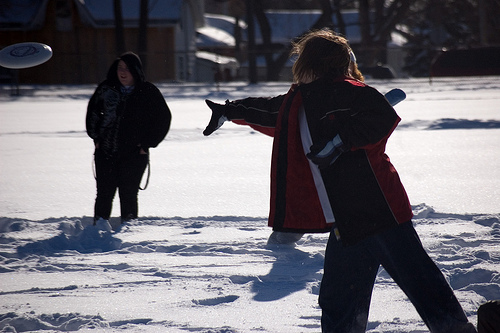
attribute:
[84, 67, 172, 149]
coat — black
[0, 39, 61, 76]
frisbee — flying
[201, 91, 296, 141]
arm — out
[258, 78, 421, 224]
jacket — red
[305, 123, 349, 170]
gloves — black, white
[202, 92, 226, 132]
gloves — black, white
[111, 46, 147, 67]
hood — black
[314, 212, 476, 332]
pants — black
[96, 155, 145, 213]
pants — black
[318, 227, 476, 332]
pants — pair , black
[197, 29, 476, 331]
person — black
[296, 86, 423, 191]
coat — red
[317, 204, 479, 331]
pants — black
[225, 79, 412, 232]
coat — red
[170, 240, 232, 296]
snow — white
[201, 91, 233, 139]
gloves — black, white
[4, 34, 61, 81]
frisbee — white 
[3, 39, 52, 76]
frisbee — plastic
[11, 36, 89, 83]
frisbee — white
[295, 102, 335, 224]
stripe — white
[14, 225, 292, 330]
snow — deep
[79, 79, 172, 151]
coat — black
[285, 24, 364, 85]
hair — red